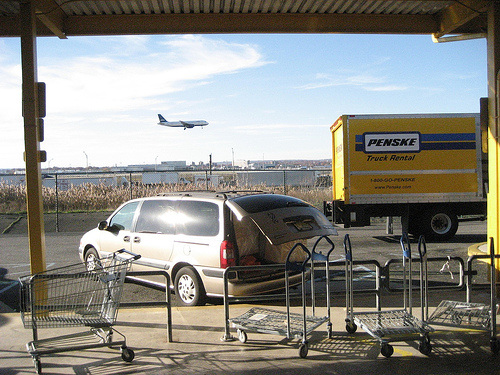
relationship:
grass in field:
[4, 181, 332, 214] [14, 170, 349, 217]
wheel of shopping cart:
[121, 346, 136, 358] [18, 244, 143, 373]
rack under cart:
[23, 326, 126, 353] [17, 244, 139, 369]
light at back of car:
[218, 240, 236, 269] [75, 188, 340, 307]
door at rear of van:
[224, 192, 336, 287] [77, 195, 318, 305]